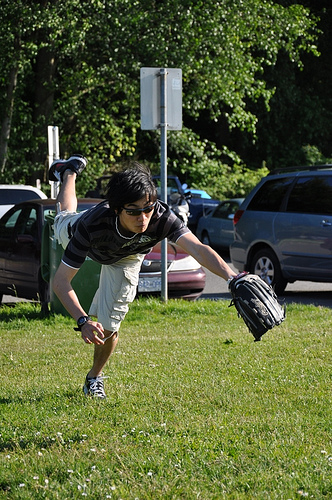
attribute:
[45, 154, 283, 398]
man — playing, leaning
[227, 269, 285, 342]
catcher's mitt — here, black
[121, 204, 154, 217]
sunglasses — black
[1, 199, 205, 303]
car — maroon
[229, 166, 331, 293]
minivan — silver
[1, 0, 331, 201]
leaves — green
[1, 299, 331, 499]
grass — short, green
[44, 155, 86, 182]
shoe — blue, athletic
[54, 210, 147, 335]
shorts — tan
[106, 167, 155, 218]
hair — black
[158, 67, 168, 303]
pole — gray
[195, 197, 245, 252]
car — silver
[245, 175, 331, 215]
window — black